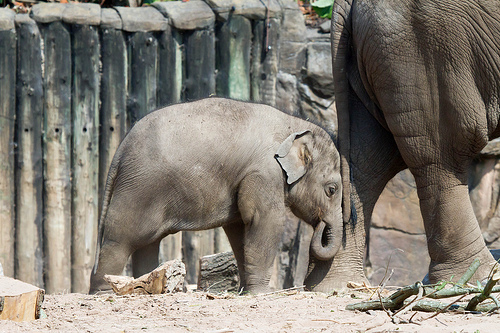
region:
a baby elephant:
[64, 66, 356, 294]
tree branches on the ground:
[338, 255, 493, 325]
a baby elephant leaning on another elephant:
[77, 99, 359, 301]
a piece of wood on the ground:
[99, 247, 186, 311]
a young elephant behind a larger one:
[47, 13, 489, 309]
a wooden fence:
[8, 34, 278, 211]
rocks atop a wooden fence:
[1, 9, 291, 87]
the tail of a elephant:
[293, 10, 388, 227]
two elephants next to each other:
[53, 22, 476, 289]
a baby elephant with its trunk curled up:
[195, 120, 366, 292]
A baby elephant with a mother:
[72, 17, 469, 288]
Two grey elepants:
[75, 49, 469, 272]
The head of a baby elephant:
[276, 109, 350, 264]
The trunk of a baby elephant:
[311, 216, 347, 261]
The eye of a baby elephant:
[323, 171, 344, 204]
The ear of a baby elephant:
[275, 124, 317, 187]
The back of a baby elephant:
[134, 92, 290, 137]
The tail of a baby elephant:
[102, 124, 124, 229]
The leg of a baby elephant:
[231, 207, 292, 295]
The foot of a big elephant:
[415, 236, 492, 303]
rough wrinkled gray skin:
[411, 34, 484, 86]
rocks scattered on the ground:
[79, 307, 129, 320]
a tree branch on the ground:
[394, 284, 457, 326]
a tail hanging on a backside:
[329, 6, 351, 143]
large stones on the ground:
[146, 266, 193, 295]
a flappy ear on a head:
[273, 129, 322, 186]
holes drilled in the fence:
[17, 120, 125, 141]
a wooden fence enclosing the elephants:
[26, 38, 86, 280]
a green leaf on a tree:
[311, 1, 336, 20]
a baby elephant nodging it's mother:
[75, 91, 350, 331]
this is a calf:
[138, 115, 335, 285]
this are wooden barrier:
[17, 27, 98, 238]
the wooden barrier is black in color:
[11, 30, 101, 209]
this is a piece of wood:
[6, 277, 44, 323]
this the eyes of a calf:
[324, 182, 344, 206]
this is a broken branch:
[354, 273, 499, 318]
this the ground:
[138, 297, 289, 331]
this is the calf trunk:
[305, 222, 345, 260]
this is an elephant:
[338, 6, 489, 166]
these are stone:
[125, 11, 206, 31]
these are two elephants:
[108, 8, 493, 288]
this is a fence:
[11, 19, 83, 280]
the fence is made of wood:
[9, 28, 96, 256]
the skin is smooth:
[172, 115, 230, 232]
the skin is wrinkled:
[439, 5, 499, 75]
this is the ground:
[101, 302, 322, 330]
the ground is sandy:
[131, 297, 268, 330]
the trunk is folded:
[308, 212, 345, 263]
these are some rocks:
[42, 3, 179, 29]